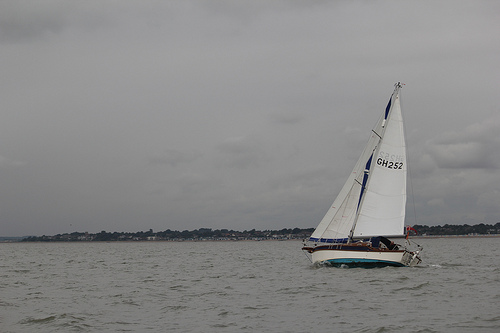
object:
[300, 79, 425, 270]
sail boat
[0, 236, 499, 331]
water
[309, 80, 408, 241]
sail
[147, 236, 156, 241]
houses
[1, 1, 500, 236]
sky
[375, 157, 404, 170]
writing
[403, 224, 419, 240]
ribbon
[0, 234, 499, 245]
shore